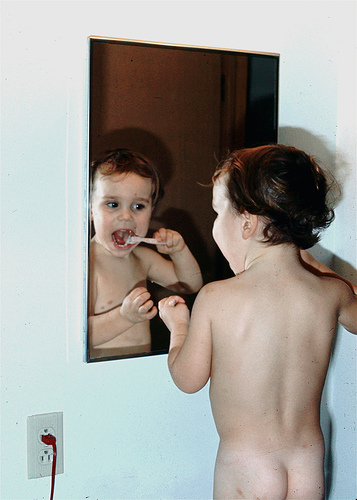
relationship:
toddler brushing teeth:
[125, 161, 356, 449] [105, 226, 138, 255]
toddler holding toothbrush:
[89, 146, 204, 362] [124, 235, 167, 245]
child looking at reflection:
[157, 142, 354, 498] [91, 144, 196, 360]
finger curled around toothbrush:
[152, 231, 163, 244] [122, 234, 166, 245]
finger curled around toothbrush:
[159, 226, 166, 241] [122, 234, 166, 245]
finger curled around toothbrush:
[166, 228, 172, 247] [122, 234, 166, 245]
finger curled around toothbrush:
[172, 233, 179, 247] [122, 234, 166, 245]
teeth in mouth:
[112, 233, 132, 246] [110, 226, 138, 249]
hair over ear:
[237, 202, 265, 215] [240, 204, 258, 242]